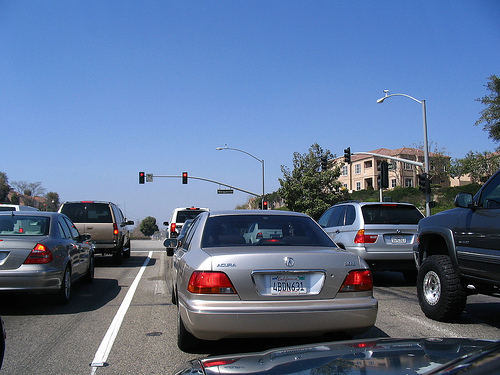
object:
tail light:
[340, 268, 374, 293]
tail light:
[170, 222, 177, 233]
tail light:
[352, 229, 382, 244]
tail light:
[112, 228, 119, 234]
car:
[313, 200, 428, 285]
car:
[172, 335, 499, 374]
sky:
[1, 3, 483, 193]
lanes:
[6, 151, 498, 371]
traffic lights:
[418, 171, 429, 179]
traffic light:
[263, 201, 268, 204]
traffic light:
[343, 147, 350, 153]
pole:
[420, 99, 433, 216]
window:
[199, 212, 340, 248]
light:
[186, 269, 238, 294]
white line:
[91, 249, 154, 374]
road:
[1, 239, 498, 374]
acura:
[165, 206, 379, 345]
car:
[411, 166, 499, 323]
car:
[53, 200, 135, 265]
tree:
[275, 142, 348, 205]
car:
[162, 209, 381, 351]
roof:
[325, 146, 450, 164]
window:
[361, 204, 428, 225]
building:
[319, 146, 438, 189]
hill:
[356, 190, 436, 200]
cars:
[163, 205, 212, 256]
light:
[182, 172, 188, 177]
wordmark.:
[215, 260, 243, 272]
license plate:
[270, 277, 309, 299]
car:
[0, 203, 42, 213]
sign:
[216, 188, 235, 193]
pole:
[261, 158, 266, 212]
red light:
[139, 172, 144, 174]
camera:
[382, 88, 389, 96]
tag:
[297, 273, 306, 280]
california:
[276, 274, 298, 283]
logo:
[283, 255, 295, 268]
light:
[24, 242, 55, 264]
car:
[0, 210, 97, 302]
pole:
[378, 163, 385, 201]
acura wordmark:
[212, 259, 237, 272]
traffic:
[1, 144, 484, 373]